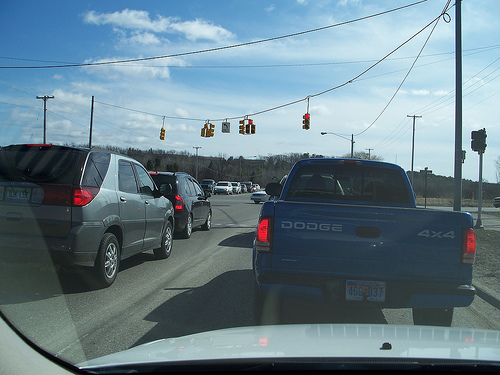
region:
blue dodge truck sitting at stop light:
[242, 149, 479, 329]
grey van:
[0, 134, 177, 288]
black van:
[135, 167, 219, 238]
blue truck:
[240, 155, 482, 327]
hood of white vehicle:
[62, 320, 497, 374]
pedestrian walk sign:
[465, 127, 489, 229]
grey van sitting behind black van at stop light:
[1, 133, 174, 290]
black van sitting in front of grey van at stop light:
[145, 162, 215, 238]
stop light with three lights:
[301, 99, 312, 134]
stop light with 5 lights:
[245, 114, 256, 137]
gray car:
[12, 124, 176, 281]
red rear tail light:
[250, 214, 276, 256]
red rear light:
[67, 187, 97, 212]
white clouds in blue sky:
[4, 8, 72, 50]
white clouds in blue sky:
[54, 4, 184, 41]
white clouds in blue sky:
[198, 15, 290, 58]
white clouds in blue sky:
[386, 17, 443, 75]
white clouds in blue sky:
[258, 24, 363, 96]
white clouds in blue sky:
[125, 55, 212, 115]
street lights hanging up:
[151, 111, 318, 137]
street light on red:
[296, 91, 319, 135]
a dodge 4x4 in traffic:
[268, 206, 473, 252]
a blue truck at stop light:
[256, 151, 480, 327]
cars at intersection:
[8, 134, 465, 308]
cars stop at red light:
[196, 159, 270, 201]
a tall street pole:
[24, 82, 88, 142]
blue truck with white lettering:
[258, 153, 471, 305]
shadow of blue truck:
[146, 253, 404, 321]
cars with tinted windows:
[2, 141, 179, 277]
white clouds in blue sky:
[8, 17, 87, 65]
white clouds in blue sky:
[75, 9, 159, 48]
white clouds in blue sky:
[223, 55, 299, 100]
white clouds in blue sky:
[321, 18, 406, 58]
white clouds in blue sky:
[331, 74, 404, 114]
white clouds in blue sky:
[389, 39, 440, 90]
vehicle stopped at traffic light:
[239, 155, 479, 314]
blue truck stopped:
[252, 146, 482, 312]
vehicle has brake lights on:
[248, 190, 490, 306]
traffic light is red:
[295, 102, 324, 139]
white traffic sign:
[218, 116, 235, 136]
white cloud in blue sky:
[80, 5, 280, 40]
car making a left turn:
[246, 172, 276, 204]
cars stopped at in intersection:
[213, 174, 259, 195]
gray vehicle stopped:
[0, 148, 166, 272]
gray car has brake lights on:
[0, 152, 177, 272]